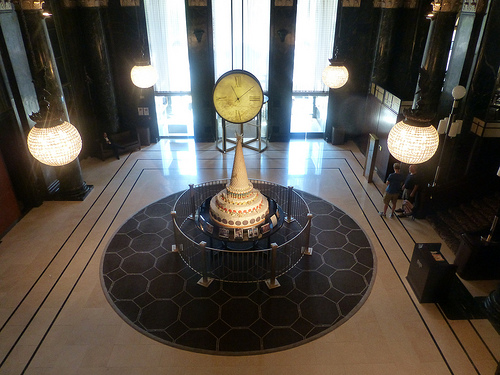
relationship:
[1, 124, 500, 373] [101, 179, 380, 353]
floor has circle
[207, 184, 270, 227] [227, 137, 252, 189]
object has cone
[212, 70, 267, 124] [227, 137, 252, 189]
clock suspended over cone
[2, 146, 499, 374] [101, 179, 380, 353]
triple lines around circle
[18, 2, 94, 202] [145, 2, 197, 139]
column in front of window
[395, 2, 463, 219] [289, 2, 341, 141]
column in front of window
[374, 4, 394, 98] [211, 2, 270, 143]
column in front of window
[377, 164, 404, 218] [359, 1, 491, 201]
person by wall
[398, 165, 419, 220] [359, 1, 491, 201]
person by wall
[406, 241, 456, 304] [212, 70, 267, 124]
reception desk facing clock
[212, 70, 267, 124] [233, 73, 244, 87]
clock has number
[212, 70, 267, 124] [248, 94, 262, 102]
clock has number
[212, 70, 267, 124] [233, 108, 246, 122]
clock has number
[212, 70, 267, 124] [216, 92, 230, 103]
clock has number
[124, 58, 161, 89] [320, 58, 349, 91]
lighted globe next to lighted globe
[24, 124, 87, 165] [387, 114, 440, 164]
lighted globe next to lighted globe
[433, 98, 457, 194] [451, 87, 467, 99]
pole holding light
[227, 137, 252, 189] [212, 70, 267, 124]
cone under clock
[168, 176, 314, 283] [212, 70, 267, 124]
railing around clock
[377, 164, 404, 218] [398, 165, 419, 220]
person next to person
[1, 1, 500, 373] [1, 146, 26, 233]
building has door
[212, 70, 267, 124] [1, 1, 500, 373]
clock in middle of building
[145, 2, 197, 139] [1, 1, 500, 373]
window in back of building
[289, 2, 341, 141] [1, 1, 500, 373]
window in back of building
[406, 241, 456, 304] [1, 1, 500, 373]
reception desk inside building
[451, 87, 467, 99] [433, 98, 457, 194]
light has pole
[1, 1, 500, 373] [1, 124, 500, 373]
building has floor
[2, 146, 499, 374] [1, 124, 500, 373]
triple lines printed on floor